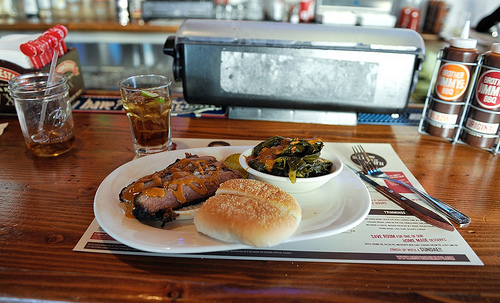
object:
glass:
[119, 74, 174, 153]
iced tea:
[120, 92, 174, 149]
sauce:
[118, 155, 221, 220]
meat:
[118, 153, 249, 223]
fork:
[349, 145, 471, 227]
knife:
[342, 152, 452, 225]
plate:
[93, 145, 375, 254]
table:
[0, 101, 497, 302]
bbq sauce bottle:
[420, 38, 477, 142]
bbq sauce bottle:
[459, 38, 499, 151]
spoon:
[31, 48, 60, 144]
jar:
[10, 73, 76, 157]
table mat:
[70, 134, 485, 267]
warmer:
[158, 16, 422, 112]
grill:
[226, 105, 355, 126]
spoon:
[22, 41, 40, 70]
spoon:
[19, 27, 69, 70]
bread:
[193, 178, 302, 251]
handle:
[378, 183, 452, 227]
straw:
[36, 46, 67, 139]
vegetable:
[248, 132, 330, 180]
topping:
[244, 133, 336, 183]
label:
[435, 61, 470, 100]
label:
[476, 66, 499, 110]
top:
[450, 19, 474, 48]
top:
[490, 32, 498, 48]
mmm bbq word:
[435, 69, 468, 96]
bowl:
[239, 145, 344, 195]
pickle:
[224, 153, 248, 177]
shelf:
[0, 0, 499, 53]